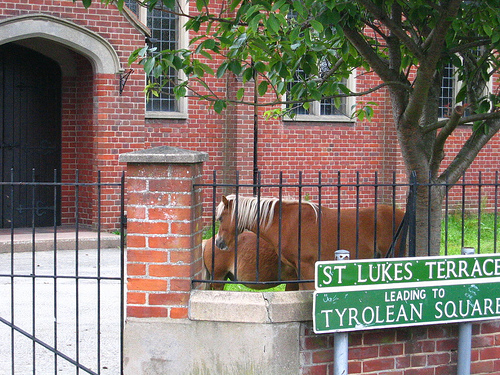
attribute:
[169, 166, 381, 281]
horses — brown, blonde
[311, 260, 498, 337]
signs — green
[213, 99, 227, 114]
leaf — green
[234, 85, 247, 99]
leaf — green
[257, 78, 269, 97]
leaf — green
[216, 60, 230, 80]
leaf — green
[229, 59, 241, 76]
leaf — green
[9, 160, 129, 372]
gates — skinney, black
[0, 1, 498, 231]
building — brick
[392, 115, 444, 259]
bark — brown, tree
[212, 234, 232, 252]
mouth — black